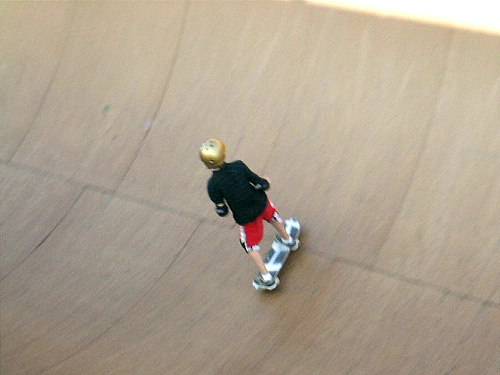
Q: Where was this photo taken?
A: At a skate park.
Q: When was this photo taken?
A: Daytime.